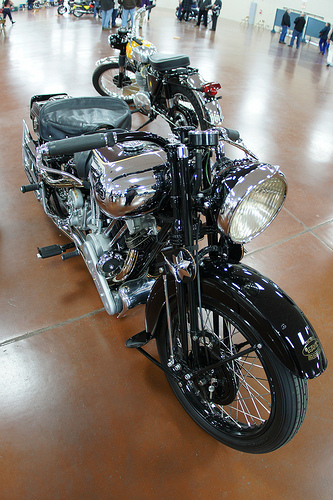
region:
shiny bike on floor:
[23, 83, 302, 427]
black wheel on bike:
[166, 263, 288, 471]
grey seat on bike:
[43, 92, 116, 144]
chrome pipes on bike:
[37, 173, 91, 261]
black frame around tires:
[141, 208, 318, 374]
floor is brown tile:
[18, 277, 115, 449]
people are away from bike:
[92, 1, 255, 65]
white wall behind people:
[226, 0, 264, 24]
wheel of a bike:
[140, 260, 313, 460]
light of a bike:
[224, 151, 295, 236]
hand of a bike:
[47, 111, 108, 156]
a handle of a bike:
[34, 132, 120, 167]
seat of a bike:
[34, 83, 132, 149]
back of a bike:
[28, 93, 125, 194]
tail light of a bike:
[198, 81, 227, 103]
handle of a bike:
[102, 20, 130, 47]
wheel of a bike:
[93, 45, 155, 103]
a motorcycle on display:
[24, 53, 294, 449]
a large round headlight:
[227, 157, 280, 276]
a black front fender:
[87, 270, 331, 372]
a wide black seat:
[34, 87, 144, 153]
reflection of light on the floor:
[15, 15, 330, 169]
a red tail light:
[201, 77, 230, 103]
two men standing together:
[263, 8, 314, 61]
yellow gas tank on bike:
[113, 34, 156, 66]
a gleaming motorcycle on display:
[20, 80, 330, 457]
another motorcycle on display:
[87, 6, 237, 152]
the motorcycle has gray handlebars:
[34, 130, 129, 161]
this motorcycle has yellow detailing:
[122, 32, 157, 67]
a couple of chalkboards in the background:
[268, 3, 332, 47]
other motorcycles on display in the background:
[55, 0, 102, 19]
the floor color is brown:
[8, 357, 137, 484]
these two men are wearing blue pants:
[275, 5, 310, 52]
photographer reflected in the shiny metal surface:
[119, 178, 143, 211]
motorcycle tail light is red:
[195, 78, 225, 98]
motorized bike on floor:
[21, 86, 308, 442]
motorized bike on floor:
[86, 3, 233, 150]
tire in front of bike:
[151, 266, 305, 450]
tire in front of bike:
[88, 52, 148, 100]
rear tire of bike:
[169, 86, 199, 132]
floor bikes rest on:
[8, 15, 322, 496]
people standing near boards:
[271, 6, 330, 65]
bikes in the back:
[53, 2, 95, 18]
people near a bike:
[168, 2, 227, 30]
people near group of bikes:
[95, 2, 163, 25]